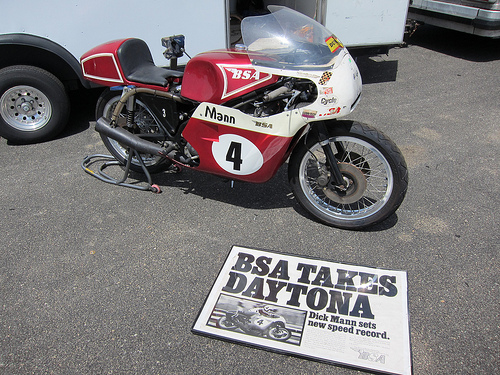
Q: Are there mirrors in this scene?
A: No, there are no mirrors.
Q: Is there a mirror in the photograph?
A: No, there are no mirrors.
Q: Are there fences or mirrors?
A: No, there are no mirrors or fences.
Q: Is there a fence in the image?
A: No, there are no fences.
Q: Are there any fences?
A: No, there are no fences.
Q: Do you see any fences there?
A: No, there are no fences.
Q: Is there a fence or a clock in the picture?
A: No, there are no fences or clocks.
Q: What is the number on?
A: The number is on the bike.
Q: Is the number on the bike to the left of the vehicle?
A: Yes, the number is on the bike.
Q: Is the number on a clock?
A: No, the number is on the bike.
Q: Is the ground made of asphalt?
A: Yes, the ground is made of asphalt.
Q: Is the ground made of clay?
A: No, the ground is made of asphalt.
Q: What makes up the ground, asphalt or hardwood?
A: The ground is made of asphalt.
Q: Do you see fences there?
A: No, there are no fences.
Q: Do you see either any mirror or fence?
A: No, there are no fences or mirrors.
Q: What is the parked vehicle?
A: The vehicle is a trailer.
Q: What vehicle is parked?
A: The vehicle is a trailer.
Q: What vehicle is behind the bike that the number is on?
A: The vehicle is a trailer.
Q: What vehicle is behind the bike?
A: The vehicle is a trailer.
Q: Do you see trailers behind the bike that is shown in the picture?
A: Yes, there is a trailer behind the bike.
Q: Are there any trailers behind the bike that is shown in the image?
A: Yes, there is a trailer behind the bike.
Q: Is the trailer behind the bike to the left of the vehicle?
A: Yes, the trailer is behind the bike.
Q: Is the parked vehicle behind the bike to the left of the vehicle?
A: Yes, the trailer is behind the bike.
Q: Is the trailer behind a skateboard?
A: No, the trailer is behind the bike.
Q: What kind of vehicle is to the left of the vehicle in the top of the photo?
A: The vehicle is a trailer.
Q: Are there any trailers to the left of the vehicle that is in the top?
A: Yes, there is a trailer to the left of the vehicle.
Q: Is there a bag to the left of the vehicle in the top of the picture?
A: No, there is a trailer to the left of the vehicle.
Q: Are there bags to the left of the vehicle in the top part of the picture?
A: No, there is a trailer to the left of the vehicle.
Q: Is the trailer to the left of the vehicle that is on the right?
A: Yes, the trailer is to the left of the vehicle.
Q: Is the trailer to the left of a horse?
A: No, the trailer is to the left of the vehicle.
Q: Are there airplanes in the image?
A: No, there are no airplanes.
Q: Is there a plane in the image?
A: No, there are no airplanes.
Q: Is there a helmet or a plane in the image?
A: No, there are no airplanes or helmets.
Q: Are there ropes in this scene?
A: No, there are no ropes.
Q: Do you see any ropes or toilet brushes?
A: No, there are no ropes or toilet brushes.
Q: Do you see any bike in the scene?
A: Yes, there is a bike.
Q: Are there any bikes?
A: Yes, there is a bike.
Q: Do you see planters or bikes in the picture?
A: Yes, there is a bike.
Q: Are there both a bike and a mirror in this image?
A: No, there is a bike but no mirrors.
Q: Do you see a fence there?
A: No, there are no fences.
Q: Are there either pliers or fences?
A: No, there are no fences or pliers.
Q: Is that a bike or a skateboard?
A: That is a bike.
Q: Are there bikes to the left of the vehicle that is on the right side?
A: Yes, there is a bike to the left of the vehicle.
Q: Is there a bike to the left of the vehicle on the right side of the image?
A: Yes, there is a bike to the left of the vehicle.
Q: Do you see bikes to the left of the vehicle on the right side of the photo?
A: Yes, there is a bike to the left of the vehicle.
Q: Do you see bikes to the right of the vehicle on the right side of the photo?
A: No, the bike is to the left of the vehicle.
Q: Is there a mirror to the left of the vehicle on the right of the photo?
A: No, there is a bike to the left of the vehicle.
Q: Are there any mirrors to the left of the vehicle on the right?
A: No, there is a bike to the left of the vehicle.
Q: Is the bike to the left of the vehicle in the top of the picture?
A: Yes, the bike is to the left of the vehicle.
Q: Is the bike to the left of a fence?
A: No, the bike is to the left of the vehicle.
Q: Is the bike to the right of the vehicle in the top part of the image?
A: No, the bike is to the left of the vehicle.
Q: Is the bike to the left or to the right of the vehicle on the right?
A: The bike is to the left of the vehicle.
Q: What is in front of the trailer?
A: The bike is in front of the trailer.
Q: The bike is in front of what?
A: The bike is in front of the trailer.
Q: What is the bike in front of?
A: The bike is in front of the trailer.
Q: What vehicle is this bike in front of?
A: The bike is in front of the trailer.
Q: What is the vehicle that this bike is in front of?
A: The vehicle is a trailer.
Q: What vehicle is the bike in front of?
A: The bike is in front of the trailer.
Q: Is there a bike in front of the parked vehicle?
A: Yes, there is a bike in front of the trailer.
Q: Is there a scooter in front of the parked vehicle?
A: No, there is a bike in front of the trailer.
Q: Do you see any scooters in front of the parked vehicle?
A: No, there is a bike in front of the trailer.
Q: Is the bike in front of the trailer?
A: Yes, the bike is in front of the trailer.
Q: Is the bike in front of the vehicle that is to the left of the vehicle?
A: Yes, the bike is in front of the trailer.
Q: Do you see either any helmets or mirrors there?
A: No, there are no mirrors or helmets.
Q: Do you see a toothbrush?
A: No, there are no toothbrushes.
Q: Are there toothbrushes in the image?
A: No, there are no toothbrushes.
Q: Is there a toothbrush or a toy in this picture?
A: No, there are no toothbrushes or toys.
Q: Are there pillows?
A: No, there are no pillows.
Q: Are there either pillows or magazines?
A: No, there are no pillows or magazines.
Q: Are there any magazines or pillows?
A: No, there are no pillows or magazines.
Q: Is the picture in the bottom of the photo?
A: Yes, the picture is in the bottom of the image.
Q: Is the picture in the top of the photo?
A: No, the picture is in the bottom of the image.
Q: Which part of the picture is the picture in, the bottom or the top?
A: The picture is in the bottom of the image.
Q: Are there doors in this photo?
A: Yes, there is a door.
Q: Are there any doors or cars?
A: Yes, there is a door.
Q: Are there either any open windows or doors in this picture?
A: Yes, there is an open door.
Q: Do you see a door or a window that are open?
A: Yes, the door is open.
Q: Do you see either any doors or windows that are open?
A: Yes, the door is open.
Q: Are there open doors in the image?
A: Yes, there is an open door.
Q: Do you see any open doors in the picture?
A: Yes, there is an open door.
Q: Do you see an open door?
A: Yes, there is an open door.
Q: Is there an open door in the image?
A: Yes, there is an open door.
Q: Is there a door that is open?
A: Yes, there is a door that is open.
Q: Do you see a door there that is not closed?
A: Yes, there is a open door.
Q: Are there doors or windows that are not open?
A: No, there is a door but it is open.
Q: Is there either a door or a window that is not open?
A: No, there is a door but it is open.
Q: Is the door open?
A: Yes, the door is open.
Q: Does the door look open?
A: Yes, the door is open.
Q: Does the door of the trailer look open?
A: Yes, the door is open.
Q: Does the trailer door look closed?
A: No, the door is open.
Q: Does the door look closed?
A: No, the door is open.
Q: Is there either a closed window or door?
A: No, there is a door but it is open.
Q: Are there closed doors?
A: No, there is a door but it is open.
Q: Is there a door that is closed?
A: No, there is a door but it is open.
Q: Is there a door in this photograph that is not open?
A: No, there is a door but it is open.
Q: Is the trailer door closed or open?
A: The door is open.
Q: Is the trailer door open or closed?
A: The door is open.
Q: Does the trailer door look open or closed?
A: The door is open.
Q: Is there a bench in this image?
A: No, there are no benches.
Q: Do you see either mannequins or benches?
A: No, there are no benches or mannequins.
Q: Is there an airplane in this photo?
A: No, there are no airplanes.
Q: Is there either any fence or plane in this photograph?
A: No, there are no airplanes or fences.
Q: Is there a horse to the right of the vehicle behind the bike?
A: No, there is a vehicle to the right of the trailer.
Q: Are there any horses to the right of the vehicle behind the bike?
A: No, there is a vehicle to the right of the trailer.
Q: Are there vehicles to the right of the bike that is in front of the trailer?
A: Yes, there is a vehicle to the right of the bike.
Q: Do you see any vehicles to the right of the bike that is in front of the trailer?
A: Yes, there is a vehicle to the right of the bike.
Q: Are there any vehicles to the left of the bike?
A: No, the vehicle is to the right of the bike.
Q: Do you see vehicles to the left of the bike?
A: No, the vehicle is to the right of the bike.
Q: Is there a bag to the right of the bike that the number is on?
A: No, there is a vehicle to the right of the bike.